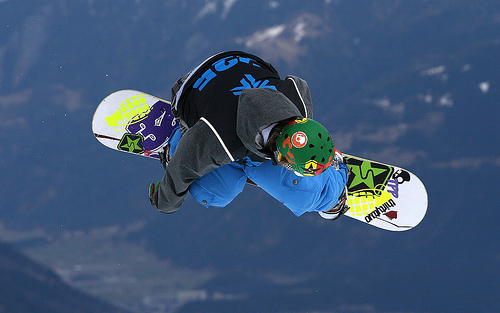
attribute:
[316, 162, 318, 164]
green — helmet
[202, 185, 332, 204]
pants — blue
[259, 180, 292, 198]
blue — pants